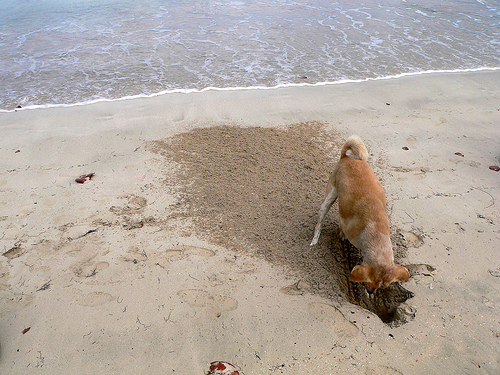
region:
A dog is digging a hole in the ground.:
[308, 137, 415, 325]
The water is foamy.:
[0, 0, 498, 111]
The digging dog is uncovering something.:
[338, 225, 410, 319]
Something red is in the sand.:
[193, 358, 250, 373]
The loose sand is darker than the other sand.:
[151, 117, 353, 316]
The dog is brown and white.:
[311, 137, 413, 293]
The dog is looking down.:
[306, 135, 413, 296]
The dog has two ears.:
[310, 135, 415, 294]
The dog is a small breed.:
[307, 135, 410, 294]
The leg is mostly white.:
[311, 153, 340, 246]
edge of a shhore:
[193, 74, 241, 115]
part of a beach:
[186, 213, 235, 293]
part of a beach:
[181, 221, 217, 286]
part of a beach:
[203, 194, 235, 246]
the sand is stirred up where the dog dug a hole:
[138, 112, 379, 317]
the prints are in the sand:
[23, 190, 248, 360]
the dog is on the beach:
[3, 68, 498, 368]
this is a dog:
[291, 125, 431, 321]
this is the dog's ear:
[340, 256, 366, 291]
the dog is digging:
[325, 257, 411, 347]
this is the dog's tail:
[325, 132, 375, 167]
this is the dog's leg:
[295, 182, 335, 270]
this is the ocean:
[0, 0, 496, 100]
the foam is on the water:
[8, 4, 497, 73]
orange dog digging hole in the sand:
[298, 122, 418, 346]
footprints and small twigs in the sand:
[34, 242, 272, 340]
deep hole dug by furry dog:
[312, 222, 427, 347]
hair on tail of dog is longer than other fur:
[334, 136, 377, 172]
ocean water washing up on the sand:
[28, 53, 440, 158]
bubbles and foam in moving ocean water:
[58, 7, 297, 82]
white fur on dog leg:
[306, 172, 356, 277]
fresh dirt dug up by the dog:
[51, 164, 303, 346]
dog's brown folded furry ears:
[346, 257, 417, 296]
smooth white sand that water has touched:
[46, 106, 177, 137]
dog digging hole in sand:
[275, 125, 428, 337]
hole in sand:
[330, 230, 426, 340]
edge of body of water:
[3, 3, 498, 115]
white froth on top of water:
[40, 92, 97, 112]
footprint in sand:
[169, 278, 243, 322]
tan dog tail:
[332, 128, 371, 164]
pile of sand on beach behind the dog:
[147, 110, 327, 258]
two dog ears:
[347, 256, 412, 286]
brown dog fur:
[345, 170, 373, 202]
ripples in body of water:
[42, 40, 139, 87]